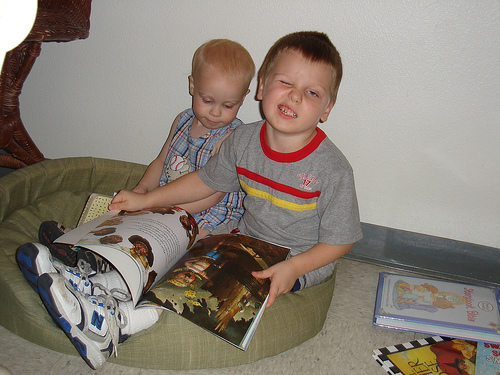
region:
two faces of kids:
[159, 44, 379, 136]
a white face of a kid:
[243, 30, 345, 156]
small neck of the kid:
[259, 137, 324, 168]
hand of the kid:
[248, 240, 361, 298]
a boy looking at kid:
[185, 64, 250, 151]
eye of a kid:
[303, 72, 323, 99]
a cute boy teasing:
[261, 40, 323, 135]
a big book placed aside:
[377, 240, 494, 335]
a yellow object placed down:
[368, 332, 436, 369]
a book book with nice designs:
[49, 205, 269, 365]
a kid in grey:
[244, 80, 315, 315]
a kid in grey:
[238, 114, 319, 354]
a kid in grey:
[310, 150, 330, 337]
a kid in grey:
[245, 40, 351, 371]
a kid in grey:
[230, 1, 315, 366]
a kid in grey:
[218, 68, 303, 358]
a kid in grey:
[233, 75, 328, 371]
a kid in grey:
[261, 50, 341, 365]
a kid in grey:
[225, 63, 322, 354]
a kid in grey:
[242, 97, 283, 369]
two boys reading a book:
[43, 25, 375, 373]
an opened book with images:
[86, 186, 286, 349]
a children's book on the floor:
[367, 257, 497, 344]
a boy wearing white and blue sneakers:
[18, 241, 133, 366]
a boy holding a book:
[101, 181, 306, 314]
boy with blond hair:
[184, 32, 259, 131]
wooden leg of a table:
[6, 0, 98, 180]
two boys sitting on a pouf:
[0, 10, 357, 360]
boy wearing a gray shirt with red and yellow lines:
[223, 125, 360, 277]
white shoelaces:
[99, 287, 126, 359]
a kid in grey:
[249, 105, 379, 342]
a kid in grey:
[234, 106, 311, 333]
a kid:
[249, 77, 328, 284]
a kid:
[275, 125, 320, 331]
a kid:
[235, 137, 314, 369]